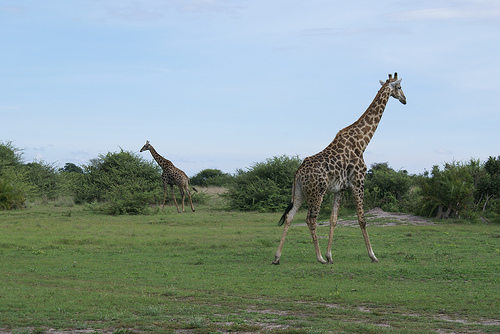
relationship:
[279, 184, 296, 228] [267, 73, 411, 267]
tail on giraffe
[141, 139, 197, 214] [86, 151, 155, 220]
giraffe near bush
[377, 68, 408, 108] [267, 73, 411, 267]
head of giraffe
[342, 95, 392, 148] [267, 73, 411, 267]
neck of giraffe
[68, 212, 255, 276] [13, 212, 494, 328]
grass on ground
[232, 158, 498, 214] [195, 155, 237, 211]
bushes near clearing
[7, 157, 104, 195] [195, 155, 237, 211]
shrubs near clearing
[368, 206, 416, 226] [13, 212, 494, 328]
dirt on ground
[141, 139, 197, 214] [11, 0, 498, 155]
giraffe under sky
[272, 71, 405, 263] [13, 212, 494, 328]
giraffe on ground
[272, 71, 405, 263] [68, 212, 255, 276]
giraffe on grass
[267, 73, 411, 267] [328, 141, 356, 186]
giraffe has spots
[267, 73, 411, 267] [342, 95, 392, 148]
giraffe has neck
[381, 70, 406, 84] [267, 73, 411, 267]
ears on giraffe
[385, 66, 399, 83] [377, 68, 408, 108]
horns on head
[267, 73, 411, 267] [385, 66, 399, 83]
giraffe has horns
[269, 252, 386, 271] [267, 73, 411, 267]
hooves on giraffe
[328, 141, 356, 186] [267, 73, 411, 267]
spots on giraffe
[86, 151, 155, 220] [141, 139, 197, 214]
bush near giraffe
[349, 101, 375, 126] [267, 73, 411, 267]
mane on giraffe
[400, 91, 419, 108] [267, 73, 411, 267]
mouth on giraffe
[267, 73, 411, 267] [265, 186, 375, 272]
giraffe has legs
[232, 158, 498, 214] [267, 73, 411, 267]
bushes behind giraffe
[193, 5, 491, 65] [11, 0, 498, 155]
clouds in sky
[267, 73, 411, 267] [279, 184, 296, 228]
giraffe has tail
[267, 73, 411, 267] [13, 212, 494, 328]
giraffe on ground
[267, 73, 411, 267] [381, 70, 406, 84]
giraffe has ears